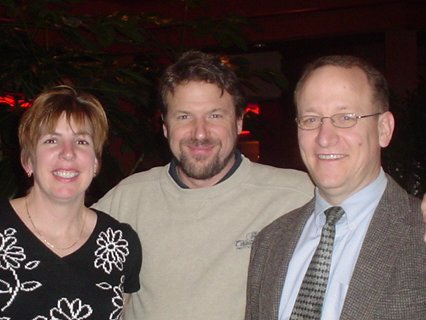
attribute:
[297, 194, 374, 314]
dress shirt — white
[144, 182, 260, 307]
sweater — tan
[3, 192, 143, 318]
shirt — black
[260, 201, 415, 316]
gray jacket — grey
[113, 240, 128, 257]
petal — flower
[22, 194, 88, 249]
necklace — gold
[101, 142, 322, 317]
shirt — light colored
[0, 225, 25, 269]
flowers — white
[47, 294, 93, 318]
flowers — white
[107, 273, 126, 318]
flowers — white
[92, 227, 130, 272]
flowers — white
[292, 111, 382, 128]
glasses — thin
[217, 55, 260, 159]
glow — red